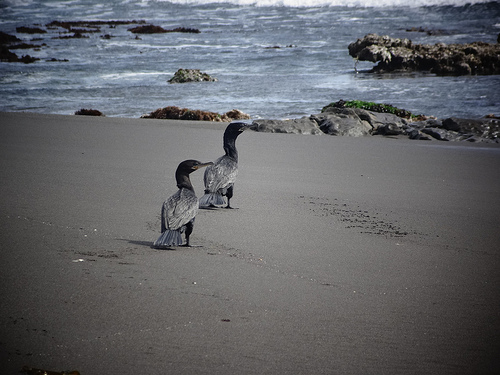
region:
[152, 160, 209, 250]
bird walking on the beach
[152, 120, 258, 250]
pair of birds walking on the beach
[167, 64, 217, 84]
rock protruding from the water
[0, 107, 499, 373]
smooth sand on the edge of the water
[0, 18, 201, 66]
cluster of rocks peeking through the water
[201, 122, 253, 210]
A bird sits on the wet sand.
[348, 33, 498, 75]
Stones stick out of the water.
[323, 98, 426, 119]
Moss is present on the rock.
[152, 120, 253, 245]
Two birds walk towards the water.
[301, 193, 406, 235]
Prints are on the sand.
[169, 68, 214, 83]
A stone stands out of the water.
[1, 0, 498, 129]
A beach has stones and plants.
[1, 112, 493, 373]
Most of the sand is wet.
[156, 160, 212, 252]
A bird has grey feathers.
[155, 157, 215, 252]
A bird looks at it's environment.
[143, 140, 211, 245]
this is a bird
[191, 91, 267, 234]
this is a bird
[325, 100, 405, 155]
this is a rock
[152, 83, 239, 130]
this is a rock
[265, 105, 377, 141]
this is a rock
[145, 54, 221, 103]
this is a rock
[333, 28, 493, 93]
this is a rock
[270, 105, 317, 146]
this is a rock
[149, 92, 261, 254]
one bird following the other toward the ocean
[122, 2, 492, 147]
ocean water with exposed rough rocks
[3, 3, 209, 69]
dark seaweed floating on water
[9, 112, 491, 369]
gray birds walking across gray sand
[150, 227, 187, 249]
straight tail feathers in a row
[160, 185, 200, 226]
oval shape of back covered in similar feathers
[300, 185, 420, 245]
short rows of marks left in sand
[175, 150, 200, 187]
curved head and neck with dark feathers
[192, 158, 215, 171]
pointed and narrow beak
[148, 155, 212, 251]
The bird in the back.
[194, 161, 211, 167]
The beak of the bird in the back.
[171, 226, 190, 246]
The legs of the bird in the back.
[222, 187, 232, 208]
The leg of the bird in the front.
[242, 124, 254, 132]
The beak of the bird in the front.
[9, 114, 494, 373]
The sand area where the birds are standing.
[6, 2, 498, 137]
The water in the distance.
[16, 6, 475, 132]
The rocks in the water.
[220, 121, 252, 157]
The bird's head that is standing in the front.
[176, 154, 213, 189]
The head of the bird standing in the back.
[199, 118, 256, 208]
The bird in the front.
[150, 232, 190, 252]
The tail feathers of the bird in the back.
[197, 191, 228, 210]
The tail feathers of the bird in the front.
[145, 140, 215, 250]
a bird in the sand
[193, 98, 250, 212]
a bird in the sand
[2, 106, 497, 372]
the sand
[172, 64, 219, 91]
a rock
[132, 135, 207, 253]
duck walking on the sand